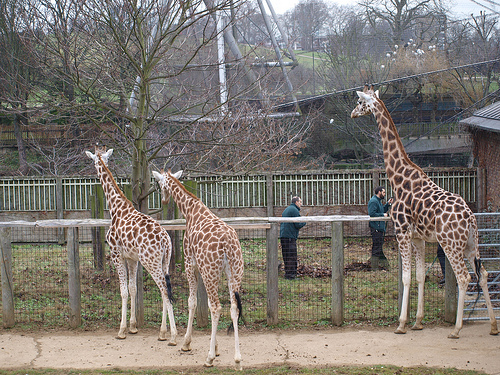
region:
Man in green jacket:
[277, 197, 304, 237]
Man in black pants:
[268, 232, 306, 271]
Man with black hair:
[368, 185, 389, 198]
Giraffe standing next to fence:
[338, 88, 482, 317]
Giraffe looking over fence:
[82, 145, 175, 309]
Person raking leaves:
[270, 188, 315, 284]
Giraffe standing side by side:
[73, 142, 258, 331]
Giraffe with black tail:
[211, 272, 266, 328]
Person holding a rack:
[366, 189, 393, 261]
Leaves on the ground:
[291, 242, 391, 307]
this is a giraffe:
[87, 140, 172, 360]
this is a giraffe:
[146, 155, 261, 361]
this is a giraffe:
[360, 78, 497, 338]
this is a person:
[277, 187, 308, 288]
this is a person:
[365, 185, 397, 276]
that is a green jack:
[276, 205, 307, 243]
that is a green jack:
[364, 195, 392, 242]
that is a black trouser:
[273, 239, 305, 289]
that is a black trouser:
[361, 229, 390, 269]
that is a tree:
[42, 11, 221, 146]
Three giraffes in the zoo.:
[101, 126, 477, 346]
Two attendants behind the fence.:
[265, 181, 409, 275]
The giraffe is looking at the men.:
[335, 88, 497, 335]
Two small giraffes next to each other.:
[81, 139, 285, 361]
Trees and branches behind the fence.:
[88, 36, 317, 181]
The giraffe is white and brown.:
[70, 72, 263, 344]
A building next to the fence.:
[460, 88, 497, 217]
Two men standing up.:
[270, 185, 400, 290]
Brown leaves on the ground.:
[291, 249, 338, 281]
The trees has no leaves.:
[42, 31, 259, 161]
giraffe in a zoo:
[345, 71, 499, 346]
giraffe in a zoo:
[146, 157, 251, 374]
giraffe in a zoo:
[79, 136, 182, 352]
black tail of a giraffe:
[160, 246, 182, 310]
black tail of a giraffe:
[225, 246, 257, 336]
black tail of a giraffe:
[468, 218, 486, 328]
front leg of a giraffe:
[388, 223, 417, 343]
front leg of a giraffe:
[405, 231, 430, 336]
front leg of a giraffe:
[171, 263, 208, 362]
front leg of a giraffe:
[112, 254, 132, 344]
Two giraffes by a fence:
[68, 126, 268, 371]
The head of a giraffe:
[342, 75, 398, 129]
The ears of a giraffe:
[147, 157, 191, 187]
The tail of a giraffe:
[460, 197, 491, 298]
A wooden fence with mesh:
[3, 209, 97, 337]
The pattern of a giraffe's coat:
[386, 157, 467, 254]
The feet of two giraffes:
[98, 305, 257, 373]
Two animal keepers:
[269, 171, 419, 308]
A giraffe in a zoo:
[267, 68, 494, 363]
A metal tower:
[114, 3, 313, 138]